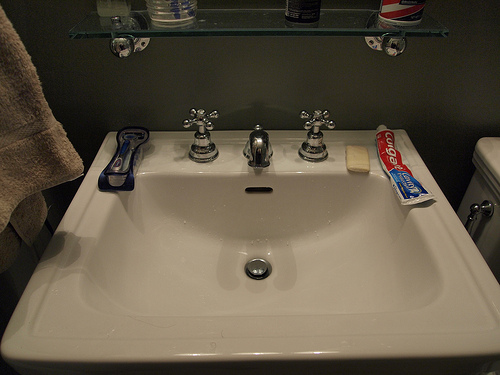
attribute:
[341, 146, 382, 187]
soap — cream colored, used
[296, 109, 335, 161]
knobs — SILVER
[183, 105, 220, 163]
knobs — SILVER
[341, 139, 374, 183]
soap — yellow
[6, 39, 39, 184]
towel — TAN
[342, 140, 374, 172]
soap — bar 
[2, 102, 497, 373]
sink — white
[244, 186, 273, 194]
drain — overflow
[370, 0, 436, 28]
can — shaving cream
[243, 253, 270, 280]
drain — silver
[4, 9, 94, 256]
towel — brown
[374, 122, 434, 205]
tube — toothpaste, large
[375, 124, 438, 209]
toothpaste — red and blue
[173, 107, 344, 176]
faucet — stainless steel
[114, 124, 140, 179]
razor — blue